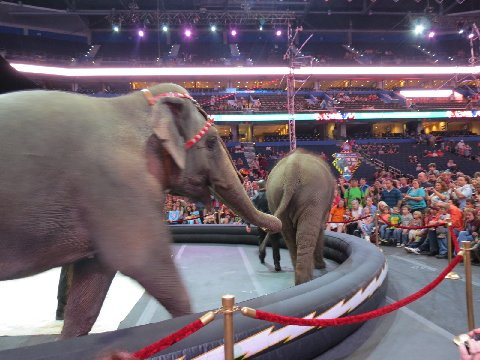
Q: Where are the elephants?
A: In a ring.